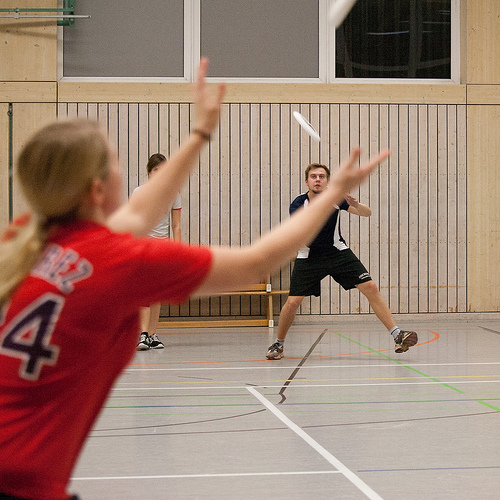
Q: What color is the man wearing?
A: Black.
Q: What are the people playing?
A: Frisbee.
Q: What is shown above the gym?
A: Windows.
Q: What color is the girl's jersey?
A: Red.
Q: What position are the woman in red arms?
A: Up.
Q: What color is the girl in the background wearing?
A: White.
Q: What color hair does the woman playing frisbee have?
A: Blond.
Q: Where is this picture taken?
A: A gym.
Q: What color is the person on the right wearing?
A: Black and white.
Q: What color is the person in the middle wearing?
A: White.